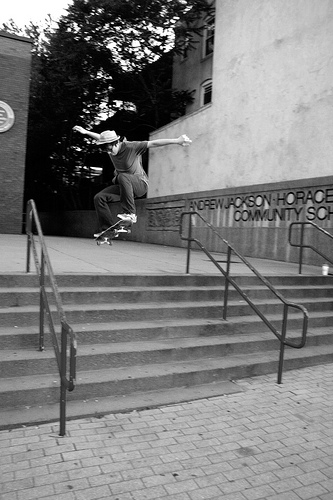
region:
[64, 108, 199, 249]
boy wearing a hat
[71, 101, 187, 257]
boy on a skate board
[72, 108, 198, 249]
boy wearing a shirt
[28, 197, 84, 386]
rail of a stair case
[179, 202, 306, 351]
rail of stair case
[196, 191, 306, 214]
writings on a wall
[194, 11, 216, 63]
window on a building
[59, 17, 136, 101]
tree near a building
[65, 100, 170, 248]
boy in air on skate board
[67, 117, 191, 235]
man in hat skating on skateboard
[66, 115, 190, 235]
man in pants and tshirt skating on skateboard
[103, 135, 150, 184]
tshirt the man is wearing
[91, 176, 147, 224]
pants the man is wearing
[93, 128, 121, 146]
hat the man is wearing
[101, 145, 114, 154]
mans sunglasses he is wearing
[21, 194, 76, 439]
stair railing in front of the man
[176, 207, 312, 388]
stair railing behind the man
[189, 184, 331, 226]
sign for a community school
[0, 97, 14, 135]
half of a round sign on the building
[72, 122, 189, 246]
the person is skateboarding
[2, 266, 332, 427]
stone set of stairs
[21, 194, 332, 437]
metal handrails on stairs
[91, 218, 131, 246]
skate board is in air nose up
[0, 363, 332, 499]
brick walk way at bottom of stairs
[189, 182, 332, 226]
building name in cement wall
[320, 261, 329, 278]
drink cup behind railing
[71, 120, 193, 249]
skate boarder is jumping stair set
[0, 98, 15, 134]
metal circle on brick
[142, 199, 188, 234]
chunk of concrete in wall is decoration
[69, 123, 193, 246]
Skateboarder in mid air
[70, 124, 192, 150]
Arms are out for balance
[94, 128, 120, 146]
Small white hat on head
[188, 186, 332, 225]
Name of building printed on side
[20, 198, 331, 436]
Three railings going down the steps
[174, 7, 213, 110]
Windows on the side of the building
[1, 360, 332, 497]
Sidewalk made of bricks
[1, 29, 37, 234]
Building is made of bricks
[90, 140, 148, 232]
Wearing a tee shirt and pants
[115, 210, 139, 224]
Wearing white skateboard sneakers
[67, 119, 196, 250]
person skateboarding in mid air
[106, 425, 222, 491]
brick side walk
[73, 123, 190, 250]
man wearing hat on skateboard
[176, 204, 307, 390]
metal safety railing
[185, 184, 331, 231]
sign on wall for builing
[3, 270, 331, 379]
steps leading down to level below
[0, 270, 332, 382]
steps leading up for level above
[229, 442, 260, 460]
stain on side walk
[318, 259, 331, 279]
cup on edge of step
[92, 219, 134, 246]
skateboard with four wheels off ground